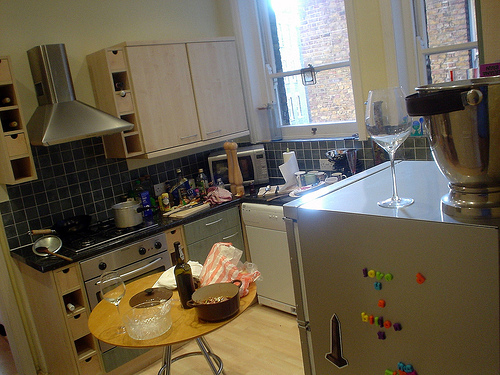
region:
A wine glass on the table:
[95, 265, 127, 335]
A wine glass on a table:
[168, 235, 196, 309]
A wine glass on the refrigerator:
[362, 82, 417, 208]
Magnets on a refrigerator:
[343, 262, 429, 343]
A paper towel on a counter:
[274, 145, 303, 182]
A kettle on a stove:
[108, 200, 160, 230]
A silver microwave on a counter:
[200, 142, 273, 191]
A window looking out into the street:
[248, 0, 362, 127]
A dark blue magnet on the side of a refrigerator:
[318, 312, 351, 368]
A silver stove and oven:
[80, 232, 172, 370]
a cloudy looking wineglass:
[365, 85, 414, 210]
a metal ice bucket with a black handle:
[404, 77, 498, 212]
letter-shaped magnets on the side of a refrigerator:
[299, 209, 497, 374]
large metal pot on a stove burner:
[108, 199, 148, 232]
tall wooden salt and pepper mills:
[221, 138, 246, 198]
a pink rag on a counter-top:
[201, 184, 236, 209]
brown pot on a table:
[185, 279, 244, 321]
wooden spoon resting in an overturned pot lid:
[31, 232, 73, 265]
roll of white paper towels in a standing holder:
[278, 145, 299, 185]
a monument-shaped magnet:
[324, 313, 348, 368]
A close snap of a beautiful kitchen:
[1, 0, 496, 372]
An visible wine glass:
[329, 82, 414, 210]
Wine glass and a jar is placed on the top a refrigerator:
[289, 60, 499, 361]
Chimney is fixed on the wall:
[15, 47, 150, 180]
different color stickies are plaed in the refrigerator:
[329, 240, 489, 372]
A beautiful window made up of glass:
[256, 8, 361, 135]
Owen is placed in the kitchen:
[209, 144, 271, 197]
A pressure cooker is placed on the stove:
[110, 188, 151, 234]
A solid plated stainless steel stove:
[68, 219, 193, 368]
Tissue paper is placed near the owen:
[277, 145, 304, 192]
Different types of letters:
[349, 251, 451, 359]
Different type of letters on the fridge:
[275, 196, 472, 364]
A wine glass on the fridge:
[356, 82, 423, 210]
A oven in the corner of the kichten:
[186, 144, 292, 199]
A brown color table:
[57, 246, 265, 346]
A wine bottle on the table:
[160, 232, 198, 312]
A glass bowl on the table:
[125, 280, 182, 340]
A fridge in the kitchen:
[267, 154, 484, 374]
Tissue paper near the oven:
[261, 147, 312, 193]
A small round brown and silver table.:
[87, 260, 257, 372]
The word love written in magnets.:
[361, 265, 393, 282]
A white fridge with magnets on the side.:
[281, 159, 497, 373]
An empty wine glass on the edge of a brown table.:
[98, 272, 132, 337]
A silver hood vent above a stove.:
[23, 42, 134, 147]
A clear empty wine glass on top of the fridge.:
[366, 83, 412, 208]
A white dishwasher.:
[236, 200, 298, 315]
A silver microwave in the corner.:
[205, 142, 270, 187]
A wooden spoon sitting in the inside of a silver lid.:
[35, 245, 72, 262]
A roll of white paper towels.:
[278, 148, 300, 185]